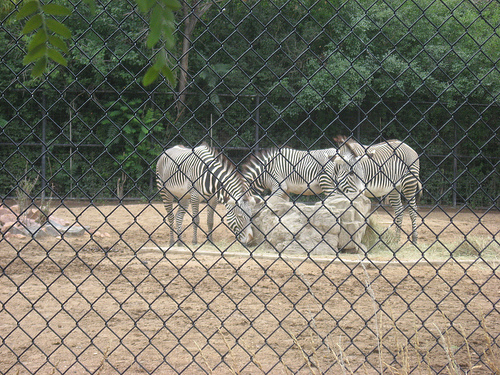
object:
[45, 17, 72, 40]
leaves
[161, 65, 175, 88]
leaves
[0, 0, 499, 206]
green bush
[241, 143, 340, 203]
stripes zebra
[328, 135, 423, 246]
stripes zebra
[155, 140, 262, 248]
stripes zebra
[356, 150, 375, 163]
zebra ear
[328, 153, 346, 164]
zebra ear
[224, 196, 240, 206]
zebra ear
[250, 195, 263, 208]
zebra ear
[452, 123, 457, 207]
trunk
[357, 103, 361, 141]
trunk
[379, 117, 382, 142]
trunk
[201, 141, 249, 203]
hair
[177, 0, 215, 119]
branch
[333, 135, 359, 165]
mane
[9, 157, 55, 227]
weeds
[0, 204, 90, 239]
rocks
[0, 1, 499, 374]
fence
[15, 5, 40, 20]
leaf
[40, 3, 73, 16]
leaf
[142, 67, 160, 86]
leaf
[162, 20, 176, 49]
leaf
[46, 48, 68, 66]
leaf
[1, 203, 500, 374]
ground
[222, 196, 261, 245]
head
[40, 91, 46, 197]
pole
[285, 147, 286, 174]
stripe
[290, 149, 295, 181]
stripe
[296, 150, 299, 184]
stripe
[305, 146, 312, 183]
stripe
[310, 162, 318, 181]
stripe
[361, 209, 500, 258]
grass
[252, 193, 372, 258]
rocks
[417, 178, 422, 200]
tail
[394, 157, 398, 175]
stripes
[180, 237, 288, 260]
grass